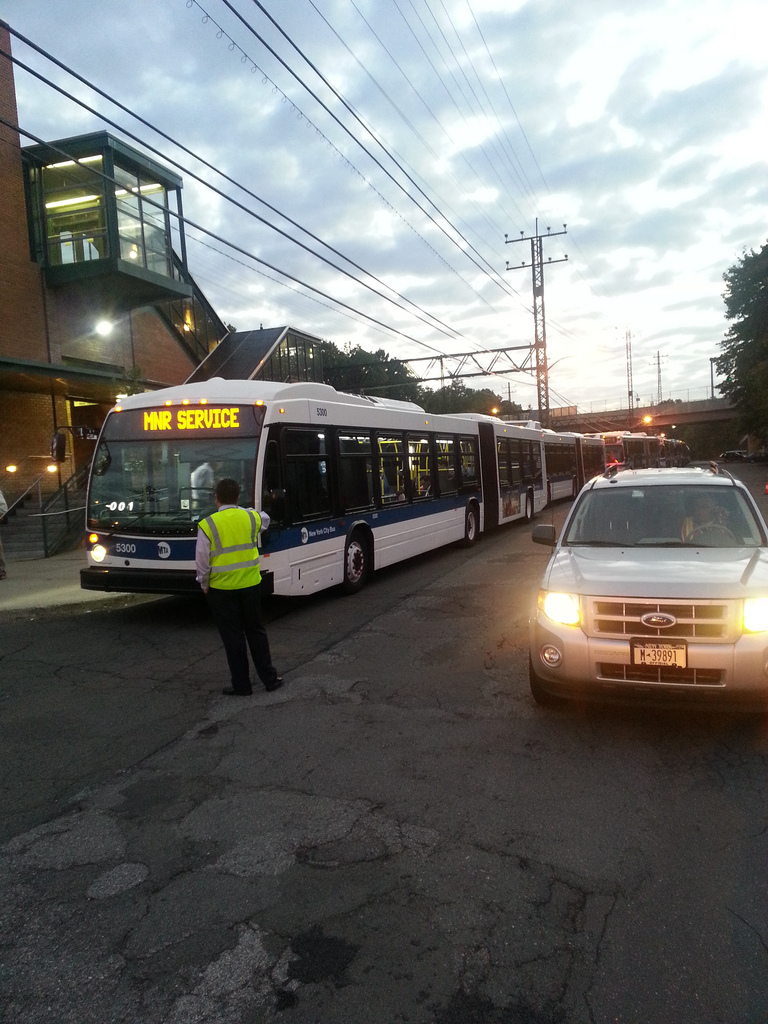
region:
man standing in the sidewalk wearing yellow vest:
[190, 477, 288, 694]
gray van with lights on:
[532, 455, 765, 701]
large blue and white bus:
[71, 374, 694, 613]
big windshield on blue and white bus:
[89, 431, 261, 536]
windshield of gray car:
[562, 476, 762, 540]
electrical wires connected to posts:
[11, 9, 691, 418]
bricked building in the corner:
[2, 36, 327, 558]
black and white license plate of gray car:
[626, 633, 686, 671]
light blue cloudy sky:
[5, 5, 755, 420]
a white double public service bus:
[77, 380, 545, 601]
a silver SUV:
[525, 464, 764, 710]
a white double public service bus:
[533, 423, 607, 503]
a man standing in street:
[192, 476, 286, 697]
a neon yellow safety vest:
[197, 508, 262, 592]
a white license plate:
[628, 640, 687, 668]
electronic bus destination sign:
[137, 408, 239, 429]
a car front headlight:
[543, 592, 580, 626]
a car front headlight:
[739, 596, 766, 632]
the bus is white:
[85, 394, 556, 627]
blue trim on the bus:
[245, 477, 477, 564]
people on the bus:
[394, 448, 445, 512]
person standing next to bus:
[162, 441, 310, 707]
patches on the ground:
[6, 714, 622, 1022]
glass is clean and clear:
[87, 439, 258, 530]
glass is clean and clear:
[380, 452, 406, 501]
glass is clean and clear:
[406, 451, 434, 500]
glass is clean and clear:
[433, 451, 456, 491]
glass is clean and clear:
[459, 445, 479, 485]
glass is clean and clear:
[377, 433, 402, 454]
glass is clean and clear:
[341, 431, 370, 447]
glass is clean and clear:
[435, 436, 458, 451]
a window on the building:
[40, 145, 184, 273]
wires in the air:
[2, 0, 558, 339]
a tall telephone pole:
[501, 224, 569, 419]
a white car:
[532, 460, 761, 703]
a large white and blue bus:
[92, 389, 576, 573]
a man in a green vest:
[192, 480, 295, 691]